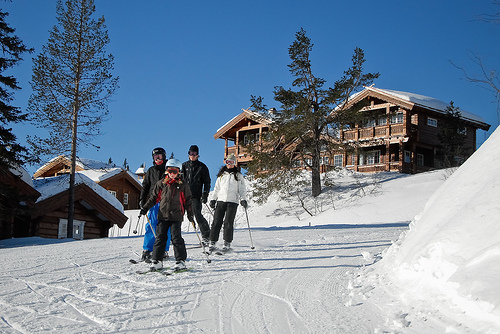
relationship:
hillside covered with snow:
[378, 129, 500, 321] [313, 182, 428, 286]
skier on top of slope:
[214, 150, 249, 258] [11, 214, 371, 316]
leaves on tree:
[288, 44, 307, 67] [244, 33, 368, 197]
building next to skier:
[29, 171, 126, 240] [214, 150, 249, 258]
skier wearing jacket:
[214, 150, 249, 258] [211, 171, 246, 204]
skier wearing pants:
[138, 148, 172, 259] [147, 202, 171, 252]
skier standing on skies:
[214, 150, 249, 258] [201, 242, 236, 258]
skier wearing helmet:
[150, 156, 192, 273] [163, 158, 185, 174]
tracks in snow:
[275, 286, 310, 318] [313, 182, 428, 286]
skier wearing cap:
[180, 144, 213, 246] [189, 143, 200, 155]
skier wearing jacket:
[138, 148, 172, 259] [141, 163, 167, 207]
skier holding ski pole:
[214, 150, 249, 258] [238, 199, 260, 253]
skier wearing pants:
[214, 150, 249, 258] [210, 198, 236, 243]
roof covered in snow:
[331, 92, 492, 133] [394, 87, 466, 113]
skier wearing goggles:
[150, 156, 192, 273] [166, 167, 181, 179]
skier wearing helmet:
[138, 148, 172, 259] [152, 146, 168, 157]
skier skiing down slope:
[214, 150, 249, 258] [11, 214, 371, 316]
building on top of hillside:
[217, 91, 486, 181] [378, 129, 500, 321]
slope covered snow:
[11, 214, 371, 316] [313, 182, 428, 286]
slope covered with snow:
[11, 214, 371, 316] [313, 182, 428, 286]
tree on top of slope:
[244, 33, 368, 197] [11, 214, 371, 316]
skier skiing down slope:
[180, 144, 213, 246] [11, 214, 371, 316]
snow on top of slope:
[313, 182, 428, 286] [11, 214, 371, 316]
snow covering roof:
[313, 182, 428, 286] [331, 92, 492, 133]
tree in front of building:
[244, 33, 368, 197] [217, 91, 486, 181]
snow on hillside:
[313, 182, 428, 286] [378, 129, 500, 321]